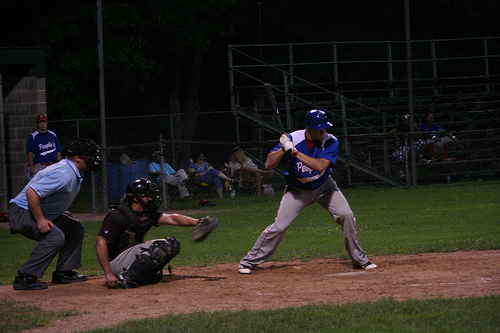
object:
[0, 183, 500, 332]
grass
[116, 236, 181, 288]
safety gear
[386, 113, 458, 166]
fans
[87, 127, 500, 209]
fence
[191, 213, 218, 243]
leather glove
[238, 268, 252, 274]
sneakers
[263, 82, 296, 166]
bat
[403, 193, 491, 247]
green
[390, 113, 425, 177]
man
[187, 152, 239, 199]
man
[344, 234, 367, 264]
wrinkles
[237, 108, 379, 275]
batter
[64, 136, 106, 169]
mask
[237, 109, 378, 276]
man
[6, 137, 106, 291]
man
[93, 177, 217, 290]
catcher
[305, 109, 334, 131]
helmet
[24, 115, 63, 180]
man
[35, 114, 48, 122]
hat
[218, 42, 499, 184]
bleachers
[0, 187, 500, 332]
field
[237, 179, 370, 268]
pants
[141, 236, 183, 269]
knee pads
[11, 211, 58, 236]
thigh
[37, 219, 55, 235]
hand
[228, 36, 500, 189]
stands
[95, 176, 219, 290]
man